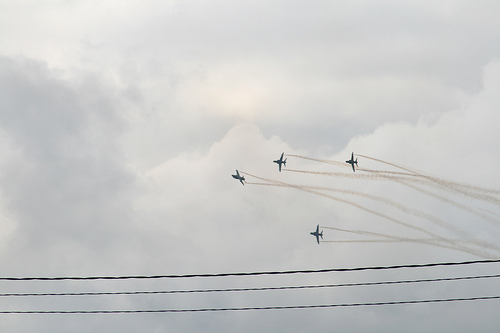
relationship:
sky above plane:
[3, 6, 497, 330] [304, 213, 334, 255]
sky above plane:
[3, 6, 497, 330] [222, 165, 250, 190]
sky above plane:
[3, 6, 497, 330] [264, 150, 293, 172]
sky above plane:
[3, 6, 497, 330] [338, 145, 373, 176]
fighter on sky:
[311, 224, 325, 244] [3, 6, 497, 330]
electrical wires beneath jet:
[1, 259, 498, 314] [343, 152, 360, 174]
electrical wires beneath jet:
[1, 259, 498, 314] [272, 152, 287, 173]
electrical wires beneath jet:
[1, 259, 498, 314] [308, 224, 325, 245]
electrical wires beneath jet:
[1, 259, 498, 314] [230, 168, 245, 186]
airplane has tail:
[272, 148, 292, 170] [283, 159, 288, 166]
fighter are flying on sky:
[311, 224, 325, 244] [143, 13, 450, 151]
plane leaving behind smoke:
[344, 150, 361, 173] [356, 165, 498, 197]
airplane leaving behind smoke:
[272, 152, 291, 170] [284, 152, 499, 229]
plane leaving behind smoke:
[229, 166, 246, 186] [356, 152, 499, 206]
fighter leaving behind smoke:
[311, 224, 325, 244] [239, 167, 497, 259]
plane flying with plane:
[338, 150, 368, 180] [272, 147, 292, 172]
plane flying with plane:
[231, 170, 245, 186] [299, 212, 342, 251]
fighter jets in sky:
[311, 224, 325, 244] [3, 6, 497, 330]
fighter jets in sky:
[107, 115, 255, 291] [42, 100, 231, 333]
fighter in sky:
[311, 224, 325, 244] [3, 6, 497, 330]